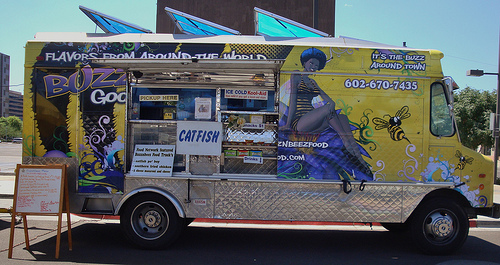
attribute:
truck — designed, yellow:
[21, 7, 494, 255]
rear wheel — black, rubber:
[119, 193, 180, 250]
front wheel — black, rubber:
[410, 197, 469, 255]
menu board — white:
[7, 164, 73, 258]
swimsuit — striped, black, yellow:
[290, 75, 321, 136]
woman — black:
[277, 57, 370, 175]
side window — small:
[128, 85, 281, 127]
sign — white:
[176, 121, 222, 156]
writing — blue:
[180, 130, 220, 144]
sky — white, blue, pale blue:
[1, 0, 500, 96]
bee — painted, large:
[373, 105, 412, 145]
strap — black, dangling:
[187, 179, 191, 203]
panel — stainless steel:
[66, 174, 453, 225]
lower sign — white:
[130, 144, 176, 177]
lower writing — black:
[135, 148, 174, 156]